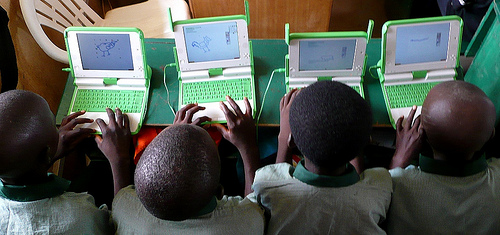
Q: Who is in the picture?
A: Kids.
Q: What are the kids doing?
A: Playing on computers.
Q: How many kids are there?
A: 4.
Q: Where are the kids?
A: At the desk.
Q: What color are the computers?
A: White and green.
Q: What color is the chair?
A: White.